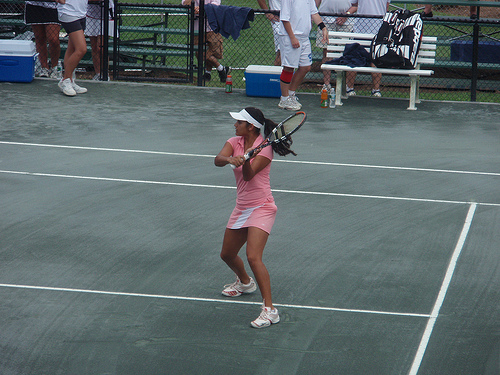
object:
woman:
[213, 104, 276, 327]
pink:
[253, 197, 283, 225]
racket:
[245, 112, 308, 156]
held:
[237, 150, 256, 167]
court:
[12, 111, 194, 338]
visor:
[226, 108, 263, 129]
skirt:
[225, 205, 273, 236]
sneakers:
[247, 306, 280, 328]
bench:
[324, 29, 436, 107]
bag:
[335, 43, 369, 74]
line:
[406, 204, 461, 374]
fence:
[202, 15, 252, 88]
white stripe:
[236, 203, 251, 228]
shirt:
[226, 135, 275, 200]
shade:
[226, 110, 242, 123]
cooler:
[0, 40, 41, 83]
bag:
[368, 9, 422, 67]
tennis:
[213, 107, 307, 331]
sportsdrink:
[224, 73, 234, 92]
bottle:
[224, 77, 234, 91]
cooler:
[243, 65, 282, 97]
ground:
[206, 87, 297, 112]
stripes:
[400, 18, 422, 64]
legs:
[404, 72, 420, 112]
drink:
[320, 85, 328, 110]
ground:
[315, 110, 372, 137]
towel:
[203, 5, 255, 40]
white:
[2, 40, 29, 54]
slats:
[323, 31, 351, 60]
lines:
[21, 125, 157, 193]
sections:
[22, 235, 198, 335]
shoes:
[220, 270, 280, 329]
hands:
[227, 148, 259, 170]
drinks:
[317, 85, 335, 108]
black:
[450, 33, 498, 66]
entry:
[102, 9, 217, 89]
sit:
[359, 45, 391, 80]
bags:
[341, 7, 423, 65]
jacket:
[201, 5, 255, 41]